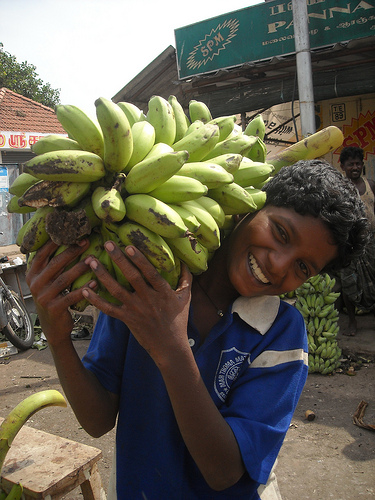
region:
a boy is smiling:
[150, 149, 362, 349]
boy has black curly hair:
[210, 149, 370, 311]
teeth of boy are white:
[239, 249, 279, 301]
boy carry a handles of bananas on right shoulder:
[15, 82, 356, 498]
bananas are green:
[0, 78, 285, 315]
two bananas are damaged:
[15, 177, 91, 249]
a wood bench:
[5, 410, 120, 498]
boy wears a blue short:
[23, 125, 364, 497]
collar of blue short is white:
[184, 286, 329, 393]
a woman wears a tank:
[336, 143, 374, 280]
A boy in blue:
[124, 339, 235, 498]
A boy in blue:
[122, 391, 207, 498]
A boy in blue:
[146, 378, 213, 489]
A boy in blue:
[162, 398, 211, 475]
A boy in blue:
[156, 332, 192, 391]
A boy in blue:
[154, 338, 232, 473]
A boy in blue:
[151, 390, 222, 479]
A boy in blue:
[126, 357, 183, 421]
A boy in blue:
[156, 372, 262, 497]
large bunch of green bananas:
[36, 99, 248, 302]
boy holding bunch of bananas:
[49, 42, 331, 478]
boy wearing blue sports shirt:
[64, 180, 284, 452]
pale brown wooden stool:
[1, 429, 111, 490]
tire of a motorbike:
[0, 302, 36, 344]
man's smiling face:
[239, 158, 337, 308]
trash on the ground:
[334, 353, 374, 455]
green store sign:
[167, 12, 360, 68]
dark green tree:
[4, 46, 60, 104]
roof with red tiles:
[2, 90, 57, 136]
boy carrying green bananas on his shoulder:
[41, 78, 357, 438]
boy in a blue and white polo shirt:
[77, 171, 339, 491]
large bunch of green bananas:
[33, 84, 270, 285]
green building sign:
[161, 9, 366, 59]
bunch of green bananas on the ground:
[295, 271, 350, 374]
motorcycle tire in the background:
[0, 267, 32, 356]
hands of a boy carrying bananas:
[27, 225, 199, 331]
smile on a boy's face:
[237, 241, 284, 296]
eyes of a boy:
[260, 216, 329, 287]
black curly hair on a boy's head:
[282, 149, 369, 257]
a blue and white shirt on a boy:
[83, 284, 321, 498]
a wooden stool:
[0, 417, 123, 491]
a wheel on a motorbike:
[0, 278, 37, 351]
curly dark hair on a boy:
[273, 156, 370, 246]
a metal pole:
[286, 0, 321, 139]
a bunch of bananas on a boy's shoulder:
[18, 96, 348, 299]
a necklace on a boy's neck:
[192, 274, 233, 324]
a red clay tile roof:
[0, 87, 76, 130]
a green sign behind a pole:
[175, 0, 365, 74]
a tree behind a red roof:
[1, 50, 59, 105]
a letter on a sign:
[266, 19, 285, 34]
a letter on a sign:
[328, 2, 350, 18]